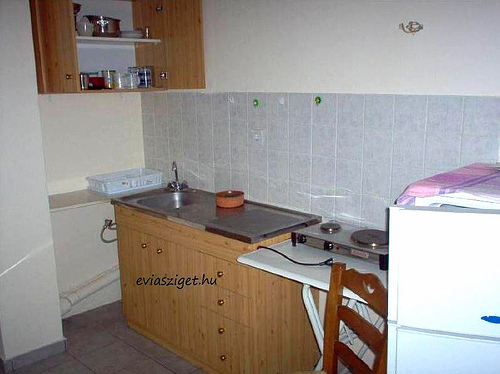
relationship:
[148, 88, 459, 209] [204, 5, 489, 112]
backsplash on wall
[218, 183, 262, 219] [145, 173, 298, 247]
bowl on counter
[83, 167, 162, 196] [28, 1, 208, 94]
basket on cabinet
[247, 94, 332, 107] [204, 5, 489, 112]
magnets on wall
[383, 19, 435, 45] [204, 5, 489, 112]
hook on wall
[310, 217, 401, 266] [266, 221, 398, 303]
burner on table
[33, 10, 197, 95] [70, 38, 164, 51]
cabinet with shelves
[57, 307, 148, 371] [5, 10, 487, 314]
tile of kitchen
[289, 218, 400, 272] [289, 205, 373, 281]
burner on counter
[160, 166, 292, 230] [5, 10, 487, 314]
faucet of kitchen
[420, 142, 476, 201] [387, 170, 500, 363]
cloth covering refrigerator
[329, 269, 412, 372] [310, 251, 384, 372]
back of chair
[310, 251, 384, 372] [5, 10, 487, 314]
chair of kitchen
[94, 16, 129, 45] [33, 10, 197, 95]
pot in cabinet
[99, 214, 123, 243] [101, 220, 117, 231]
piping with valves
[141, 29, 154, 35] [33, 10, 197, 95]
glasses in cabinet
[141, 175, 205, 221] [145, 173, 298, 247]
sink of counter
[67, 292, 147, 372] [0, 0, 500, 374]
floor of kitchen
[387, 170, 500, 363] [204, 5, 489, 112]
refrigerator by wall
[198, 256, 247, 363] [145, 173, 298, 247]
drawers beneath counter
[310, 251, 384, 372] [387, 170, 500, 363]
chair by refrigerator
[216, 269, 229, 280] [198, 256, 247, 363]
handle of drawers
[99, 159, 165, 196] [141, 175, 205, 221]
basket by sink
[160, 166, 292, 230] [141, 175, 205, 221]
faucet of sink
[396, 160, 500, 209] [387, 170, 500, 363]
cloth on top of refrigerator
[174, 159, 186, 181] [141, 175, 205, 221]
spout on sink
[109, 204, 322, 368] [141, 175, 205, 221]
cabinets under sink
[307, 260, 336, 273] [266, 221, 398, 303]
plug on table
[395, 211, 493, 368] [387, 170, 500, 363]
door of refrigerator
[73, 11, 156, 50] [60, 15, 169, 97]
containers on shelf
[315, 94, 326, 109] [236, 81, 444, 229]
circle on tile